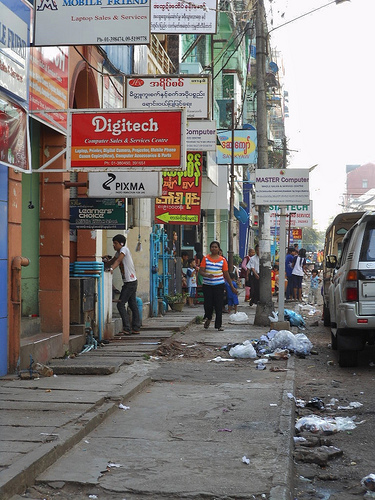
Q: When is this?
A: Daytime.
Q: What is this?
A: A street.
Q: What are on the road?
A: Rubbish bags.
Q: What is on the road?
A: Vehicles.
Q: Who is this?
A: A woman.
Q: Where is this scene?
A: In a dirty urban street.